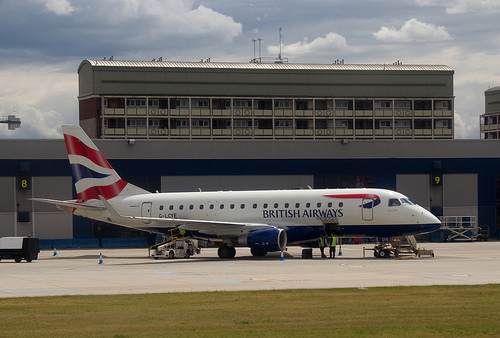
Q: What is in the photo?
A: Airplane.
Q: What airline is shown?
A: British airways.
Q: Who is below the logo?
A: Workers.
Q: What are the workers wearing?
A: Yellow vests.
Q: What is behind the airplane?
A: Airport.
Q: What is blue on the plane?
A: Engine.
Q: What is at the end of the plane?
A: Tail.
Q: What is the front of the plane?
A: Nose.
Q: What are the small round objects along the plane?
A: Windows.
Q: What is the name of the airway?
A: British.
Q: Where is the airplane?
A: Airport.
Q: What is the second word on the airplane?
A: Airways.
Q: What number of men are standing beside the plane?
A: 2.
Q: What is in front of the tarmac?
A: Grass.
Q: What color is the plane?
A: Red, white and blue.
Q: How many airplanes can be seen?
A: One.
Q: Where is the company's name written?
A: On the side of the plane.